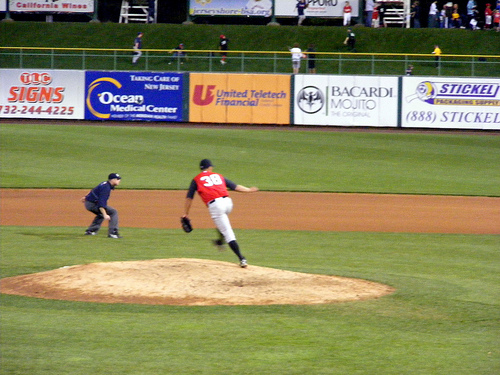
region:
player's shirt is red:
[184, 159, 280, 271]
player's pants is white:
[164, 145, 269, 270]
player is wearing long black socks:
[159, 129, 276, 296]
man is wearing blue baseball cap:
[72, 153, 144, 244]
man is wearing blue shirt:
[63, 159, 125, 250]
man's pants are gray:
[78, 152, 143, 248]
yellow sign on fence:
[185, 71, 293, 128]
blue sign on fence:
[85, 65, 187, 118]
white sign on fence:
[291, 70, 395, 129]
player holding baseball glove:
[171, 152, 287, 262]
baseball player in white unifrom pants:
[198, 193, 239, 245]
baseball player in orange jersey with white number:
[187, 167, 235, 213]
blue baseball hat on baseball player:
[197, 158, 212, 171]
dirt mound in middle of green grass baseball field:
[5, 250, 395, 307]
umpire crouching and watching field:
[83, 168, 130, 240]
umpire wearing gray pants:
[83, 199, 116, 231]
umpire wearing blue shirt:
[79, 180, 114, 208]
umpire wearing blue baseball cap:
[106, 170, 127, 178]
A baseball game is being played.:
[0, 0, 499, 374]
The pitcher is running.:
[173, 153, 275, 268]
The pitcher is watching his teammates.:
[170, 155, 263, 272]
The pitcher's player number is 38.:
[198, 171, 223, 188]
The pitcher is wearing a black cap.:
[197, 158, 215, 171]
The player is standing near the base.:
[79, 168, 121, 240]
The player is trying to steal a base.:
[81, 166, 127, 241]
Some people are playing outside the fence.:
[119, 23, 366, 70]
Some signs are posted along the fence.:
[0, 57, 498, 137]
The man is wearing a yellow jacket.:
[430, 42, 444, 61]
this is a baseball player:
[187, 153, 256, 268]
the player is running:
[179, 159, 258, 257]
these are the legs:
[213, 213, 245, 265]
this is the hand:
[176, 189, 200, 236]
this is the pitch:
[342, 295, 439, 372]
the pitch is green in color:
[259, 310, 343, 374]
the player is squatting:
[72, 167, 132, 239]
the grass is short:
[332, 307, 430, 369]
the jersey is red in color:
[202, 173, 222, 195]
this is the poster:
[374, 82, 420, 112]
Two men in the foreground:
[65, 147, 275, 274]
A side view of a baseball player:
[66, 157, 136, 247]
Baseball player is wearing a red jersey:
[170, 145, 270, 275]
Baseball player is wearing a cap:
[185, 148, 225, 173]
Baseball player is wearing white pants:
[201, 190, 251, 255]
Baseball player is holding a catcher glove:
[175, 206, 197, 237]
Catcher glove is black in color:
[172, 207, 198, 235]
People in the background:
[116, 22, 454, 72]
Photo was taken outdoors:
[1, 5, 496, 365]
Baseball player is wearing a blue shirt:
[69, 164, 131, 244]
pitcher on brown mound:
[172, 145, 264, 275]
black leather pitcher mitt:
[175, 208, 191, 236]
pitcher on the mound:
[175, 124, 314, 267]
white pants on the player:
[183, 200, 266, 255]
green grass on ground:
[363, 256, 465, 320]